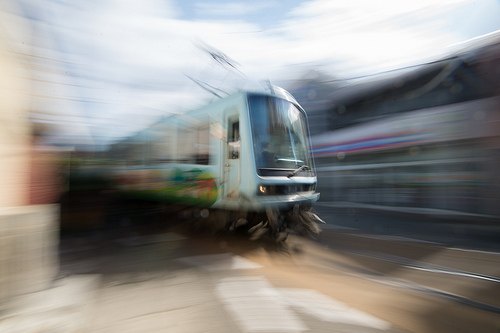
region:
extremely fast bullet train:
[87, 76, 353, 289]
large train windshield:
[241, 83, 328, 225]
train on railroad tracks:
[91, 76, 348, 263]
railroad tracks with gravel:
[341, 238, 488, 319]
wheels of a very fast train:
[121, 198, 310, 250]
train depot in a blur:
[11, 46, 80, 305]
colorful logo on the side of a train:
[103, 171, 234, 211]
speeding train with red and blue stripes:
[320, 57, 486, 174]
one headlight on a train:
[256, 177, 328, 202]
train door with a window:
[218, 98, 250, 210]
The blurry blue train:
[68, 75, 322, 248]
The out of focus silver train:
[289, 32, 497, 163]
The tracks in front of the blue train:
[283, 237, 498, 319]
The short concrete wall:
[1, 197, 68, 305]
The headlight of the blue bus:
[258, 181, 268, 195]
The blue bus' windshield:
[244, 93, 316, 180]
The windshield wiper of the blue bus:
[283, 161, 313, 180]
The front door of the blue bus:
[219, 107, 246, 199]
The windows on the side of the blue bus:
[103, 119, 218, 175]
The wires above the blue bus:
[34, 28, 251, 110]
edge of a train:
[237, 116, 254, 156]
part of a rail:
[387, 240, 441, 288]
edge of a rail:
[411, 280, 446, 303]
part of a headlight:
[238, 182, 283, 207]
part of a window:
[260, 120, 292, 151]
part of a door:
[217, 158, 249, 227]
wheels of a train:
[178, 200, 214, 230]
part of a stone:
[18, 223, 72, 285]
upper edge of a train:
[188, 80, 232, 109]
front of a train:
[247, 118, 315, 214]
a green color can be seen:
[182, 171, 186, 178]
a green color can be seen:
[71, 157, 88, 162]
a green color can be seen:
[185, 186, 189, 191]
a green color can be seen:
[161, 185, 170, 193]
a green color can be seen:
[203, 197, 214, 204]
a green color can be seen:
[194, 170, 211, 188]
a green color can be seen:
[153, 187, 162, 195]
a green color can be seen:
[171, 178, 178, 185]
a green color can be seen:
[351, 157, 361, 163]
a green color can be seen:
[66, 155, 91, 167]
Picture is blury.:
[37, 37, 453, 251]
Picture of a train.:
[91, 73, 437, 239]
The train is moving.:
[68, 70, 493, 136]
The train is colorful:
[71, 160, 280, 213]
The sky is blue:
[117, 11, 453, 36]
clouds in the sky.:
[200, 26, 392, 48]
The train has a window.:
[244, 78, 348, 178]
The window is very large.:
[226, 76, 354, 250]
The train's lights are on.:
[232, 172, 327, 200]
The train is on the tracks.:
[151, 198, 383, 260]